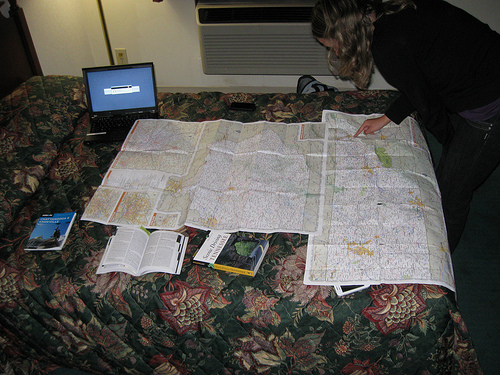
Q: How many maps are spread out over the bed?
A: Two.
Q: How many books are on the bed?
A: Three.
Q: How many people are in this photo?
A: One.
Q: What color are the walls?
A: White.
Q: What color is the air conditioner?
A: White.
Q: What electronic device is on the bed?
A: Laptop computer.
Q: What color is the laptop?
A: Black.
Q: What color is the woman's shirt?
A: Black.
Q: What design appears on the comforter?
A: Flowers.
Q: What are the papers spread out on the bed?
A: Travel maps.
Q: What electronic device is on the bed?
A: Laptop computer.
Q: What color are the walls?
A: White.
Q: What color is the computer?
A: Black.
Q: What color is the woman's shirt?
A: Black.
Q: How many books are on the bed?
A: Three.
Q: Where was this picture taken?
A: Hotel room.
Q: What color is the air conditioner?
A: White.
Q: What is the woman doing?
A: Reading a map.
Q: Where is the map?
A: On the bed.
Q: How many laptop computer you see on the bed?
A: Only one.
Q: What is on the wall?
A: Ac unit.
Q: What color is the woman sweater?
A: All black.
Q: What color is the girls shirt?
A: Black.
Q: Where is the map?
A: On the bed.